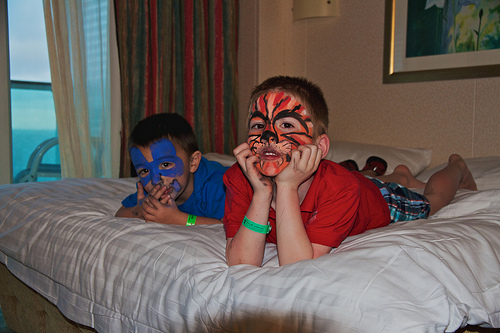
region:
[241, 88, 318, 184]
boy has face painted like a tiger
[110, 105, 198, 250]
oy has blue mask painted on face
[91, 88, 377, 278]
boys are laying on the bed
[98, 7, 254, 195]
red and green curtains hanging by the window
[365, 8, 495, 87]
picture hanging on the wall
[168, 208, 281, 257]
oys are wearing green bands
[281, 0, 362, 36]
light on the wall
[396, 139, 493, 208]
boy has bare feet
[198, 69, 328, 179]
the head of a little boy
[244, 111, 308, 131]
the eyes of a little boy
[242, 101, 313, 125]
the eyebrows of a little boy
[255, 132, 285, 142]
the nose of a little boy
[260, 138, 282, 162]
the mouth of a little boy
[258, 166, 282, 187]
the chin of a little boy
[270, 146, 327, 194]
the left hand of a little boy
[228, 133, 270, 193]
the right hand of a little boy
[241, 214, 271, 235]
green wrist band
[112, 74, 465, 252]
two boys on bed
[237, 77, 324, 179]
red and black painting on boy's face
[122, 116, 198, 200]
blue paint on boy's face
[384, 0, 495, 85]
part of picture frame on the wall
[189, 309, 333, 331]
part of shadow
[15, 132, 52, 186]
part of plastic chair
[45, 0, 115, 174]
part of white curtains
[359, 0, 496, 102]
a pitcher on a wall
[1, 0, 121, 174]
a window to the outside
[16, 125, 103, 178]
a chair back outside the window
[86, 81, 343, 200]
two boys wearing face paint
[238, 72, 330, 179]
a boy with orange and black face paint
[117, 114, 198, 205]
a boy with blue face paint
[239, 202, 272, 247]
a green wrist band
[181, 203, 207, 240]
a green wrist band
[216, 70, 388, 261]
a boy wearing a red shirt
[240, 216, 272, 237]
green wristband on boy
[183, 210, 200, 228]
light green wristband on boy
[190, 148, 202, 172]
the boy's left ear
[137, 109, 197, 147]
black hair on boys head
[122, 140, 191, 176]
blue paint on face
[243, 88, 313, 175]
red and orange paint on face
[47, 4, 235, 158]
curtains on window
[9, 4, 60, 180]
window in the room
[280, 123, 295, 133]
the boys left eye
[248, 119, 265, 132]
the boys right eye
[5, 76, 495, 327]
Two boys sitting on a bed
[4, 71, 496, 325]
Two boys with painted faces on the bed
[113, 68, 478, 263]
Two boys with painted faces lying down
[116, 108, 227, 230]
Boy in blue shirt with blue face paint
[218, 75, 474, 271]
Boy in red shirt with red face paint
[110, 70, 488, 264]
Two boys with green bands around their wrists